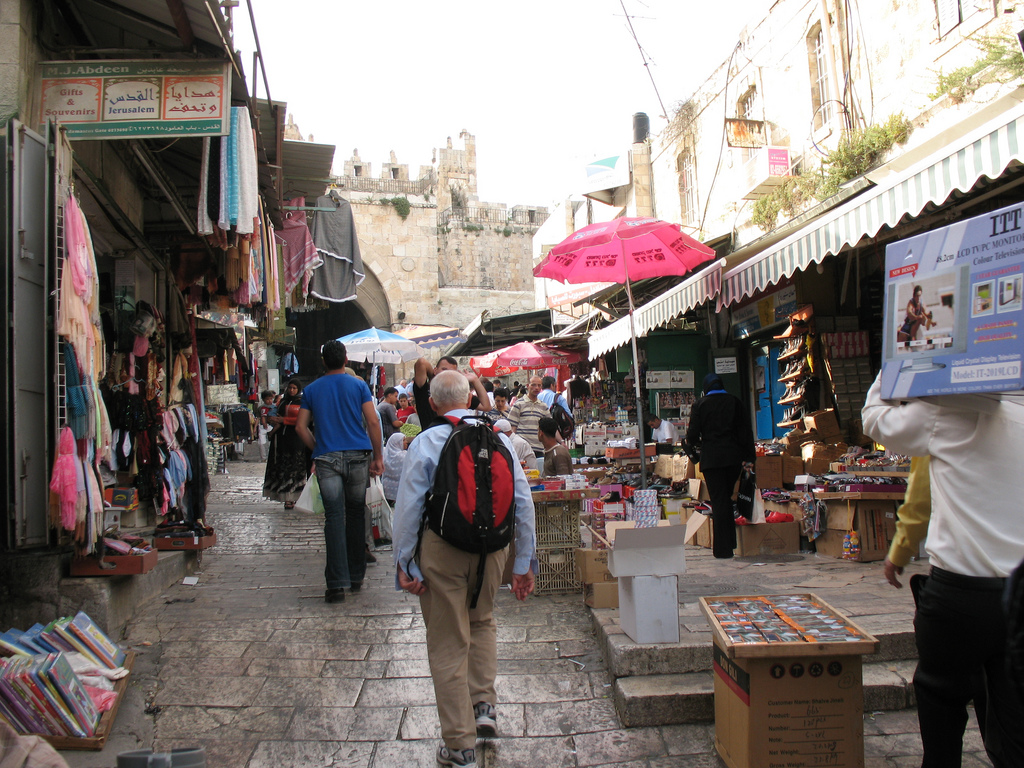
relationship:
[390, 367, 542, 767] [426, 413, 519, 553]
man has backback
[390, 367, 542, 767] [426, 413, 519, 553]
man has a backback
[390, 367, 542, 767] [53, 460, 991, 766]
man walks through a street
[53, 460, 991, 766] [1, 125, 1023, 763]
street has vendors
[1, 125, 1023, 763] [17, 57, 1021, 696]
vendors sell things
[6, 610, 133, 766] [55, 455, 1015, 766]
items are on ground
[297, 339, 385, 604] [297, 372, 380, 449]
man wearing shirt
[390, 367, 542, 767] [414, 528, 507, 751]
man wearing slacks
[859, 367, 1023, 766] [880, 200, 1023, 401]
man carrying box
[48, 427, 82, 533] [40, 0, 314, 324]
scarf hanging by roof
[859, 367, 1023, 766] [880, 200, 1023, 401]
man carries box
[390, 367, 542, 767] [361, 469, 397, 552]
man has a shopping bag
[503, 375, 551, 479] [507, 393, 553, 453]
man has shirt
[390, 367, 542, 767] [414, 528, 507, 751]
man wears slacks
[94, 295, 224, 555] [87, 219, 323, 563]
clothing for sale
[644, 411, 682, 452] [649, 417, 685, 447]
man wearing shirt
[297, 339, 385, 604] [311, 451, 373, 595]
man wearing jeans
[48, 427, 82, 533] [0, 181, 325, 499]
scarf on display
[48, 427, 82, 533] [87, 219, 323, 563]
scarf for sale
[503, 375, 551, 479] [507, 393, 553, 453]
man wearing shirt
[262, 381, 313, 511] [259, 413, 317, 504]
woman wearing skirt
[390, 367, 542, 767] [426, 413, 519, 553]
man wearing backback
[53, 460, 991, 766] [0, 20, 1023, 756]
walkway in market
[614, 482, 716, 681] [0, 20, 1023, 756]
packages are in market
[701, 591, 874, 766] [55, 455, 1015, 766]
box on ground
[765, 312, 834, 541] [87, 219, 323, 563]
shoes are for sale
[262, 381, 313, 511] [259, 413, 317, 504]
woman wearing dress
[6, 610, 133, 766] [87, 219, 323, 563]
items are for sale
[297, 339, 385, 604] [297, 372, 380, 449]
man wears shirt